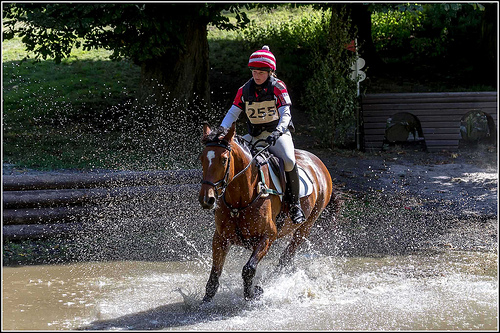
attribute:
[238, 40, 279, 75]
knitted hat — red, white, striped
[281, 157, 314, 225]
black boot — long, leather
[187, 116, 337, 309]
horse in the water — brown, black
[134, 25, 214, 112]
tree trunk — thick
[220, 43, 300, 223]
woman — competitor